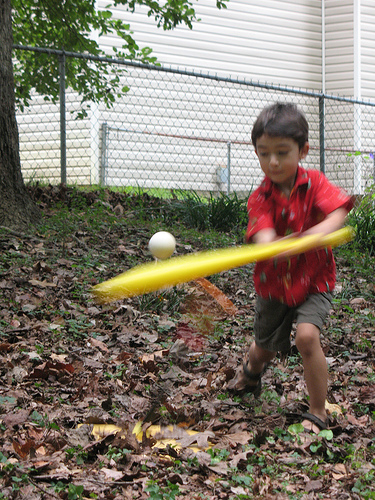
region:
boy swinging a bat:
[98, 109, 343, 427]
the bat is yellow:
[91, 226, 359, 298]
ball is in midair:
[144, 230, 194, 260]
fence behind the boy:
[9, 39, 373, 207]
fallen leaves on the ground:
[16, 311, 232, 484]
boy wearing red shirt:
[248, 170, 349, 298]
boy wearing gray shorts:
[248, 293, 342, 349]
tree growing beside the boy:
[2, 0, 120, 231]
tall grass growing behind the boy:
[177, 193, 247, 232]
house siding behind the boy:
[13, 0, 374, 189]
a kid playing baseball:
[88, 93, 363, 438]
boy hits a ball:
[82, 86, 360, 448]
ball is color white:
[137, 220, 187, 263]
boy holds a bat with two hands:
[76, 99, 364, 359]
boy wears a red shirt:
[223, 92, 365, 438]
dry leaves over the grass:
[4, 218, 369, 497]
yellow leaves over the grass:
[81, 412, 210, 461]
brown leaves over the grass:
[57, 336, 194, 403]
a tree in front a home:
[3, 0, 219, 204]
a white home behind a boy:
[11, 2, 373, 194]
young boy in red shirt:
[225, 103, 336, 441]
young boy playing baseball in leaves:
[223, 102, 338, 445]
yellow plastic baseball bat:
[94, 226, 352, 299]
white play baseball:
[149, 229, 176, 259]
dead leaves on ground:
[14, 221, 372, 497]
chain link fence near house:
[9, 42, 374, 214]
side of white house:
[23, 1, 373, 191]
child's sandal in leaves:
[290, 411, 330, 453]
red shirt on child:
[246, 164, 353, 308]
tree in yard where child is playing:
[2, 1, 203, 214]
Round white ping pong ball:
[141, 225, 183, 264]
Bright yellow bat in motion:
[86, 223, 360, 309]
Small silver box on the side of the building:
[212, 164, 232, 190]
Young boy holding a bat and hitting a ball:
[220, 90, 346, 432]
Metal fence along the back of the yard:
[7, 39, 373, 208]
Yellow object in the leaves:
[71, 410, 217, 464]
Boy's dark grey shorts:
[254, 286, 330, 356]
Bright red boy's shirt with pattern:
[236, 175, 355, 306]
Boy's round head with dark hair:
[238, 103, 321, 186]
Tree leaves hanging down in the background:
[0, 3, 238, 109]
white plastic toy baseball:
[148, 230, 176, 256]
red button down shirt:
[248, 170, 345, 295]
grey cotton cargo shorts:
[249, 287, 336, 345]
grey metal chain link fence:
[2, 44, 374, 200]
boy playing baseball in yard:
[242, 103, 341, 442]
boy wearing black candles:
[235, 102, 341, 430]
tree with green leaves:
[0, 1, 180, 196]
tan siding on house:
[4, 3, 374, 188]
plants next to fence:
[114, 187, 374, 242]